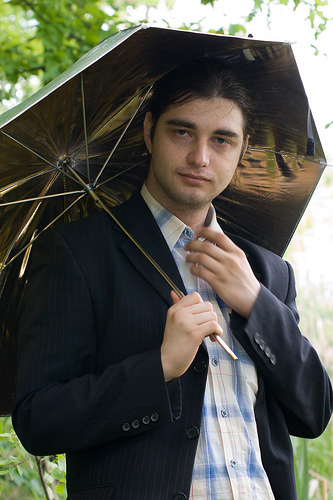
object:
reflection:
[229, 118, 323, 204]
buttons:
[211, 356, 218, 366]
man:
[12, 56, 332, 499]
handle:
[211, 333, 238, 361]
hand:
[185, 226, 261, 317]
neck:
[144, 175, 210, 239]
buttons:
[230, 458, 238, 467]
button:
[185, 423, 198, 439]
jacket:
[10, 189, 332, 500]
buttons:
[130, 417, 141, 428]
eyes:
[167, 121, 193, 140]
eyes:
[211, 132, 231, 151]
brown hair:
[149, 56, 256, 141]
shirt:
[138, 179, 277, 500]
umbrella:
[0, 25, 327, 418]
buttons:
[121, 421, 130, 430]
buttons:
[271, 354, 277, 365]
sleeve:
[12, 228, 183, 458]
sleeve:
[226, 267, 333, 439]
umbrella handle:
[66, 164, 237, 363]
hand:
[156, 288, 223, 379]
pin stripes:
[143, 425, 165, 500]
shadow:
[0, 26, 154, 275]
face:
[153, 91, 243, 205]